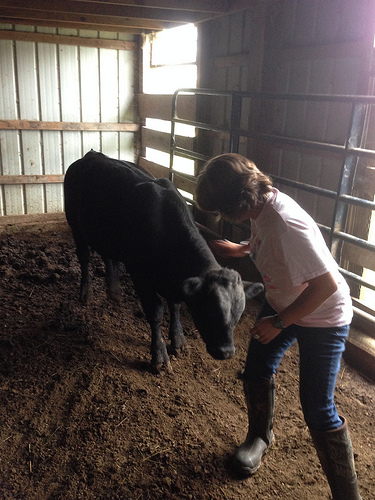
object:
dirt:
[90, 315, 132, 368]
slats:
[0, 29, 143, 225]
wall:
[0, 20, 145, 223]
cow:
[62, 147, 264, 377]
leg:
[147, 288, 171, 361]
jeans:
[243, 298, 349, 434]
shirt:
[241, 184, 354, 326]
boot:
[235, 369, 277, 475]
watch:
[267, 312, 288, 331]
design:
[252, 241, 286, 294]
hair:
[195, 151, 274, 218]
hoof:
[172, 328, 189, 353]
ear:
[184, 278, 206, 299]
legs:
[72, 228, 94, 282]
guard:
[167, 81, 372, 247]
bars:
[169, 86, 375, 321]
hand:
[210, 237, 237, 258]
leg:
[244, 307, 292, 439]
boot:
[315, 418, 362, 499]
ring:
[254, 334, 260, 340]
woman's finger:
[250, 319, 270, 344]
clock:
[273, 313, 283, 329]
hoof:
[151, 356, 173, 375]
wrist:
[267, 313, 286, 331]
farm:
[0, 287, 373, 495]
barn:
[1, 35, 374, 498]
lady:
[193, 154, 359, 500]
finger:
[242, 322, 263, 361]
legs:
[170, 296, 186, 342]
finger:
[249, 318, 269, 344]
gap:
[243, 424, 265, 444]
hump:
[138, 169, 172, 201]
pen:
[0, 21, 372, 409]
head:
[180, 265, 265, 359]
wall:
[137, 0, 374, 383]